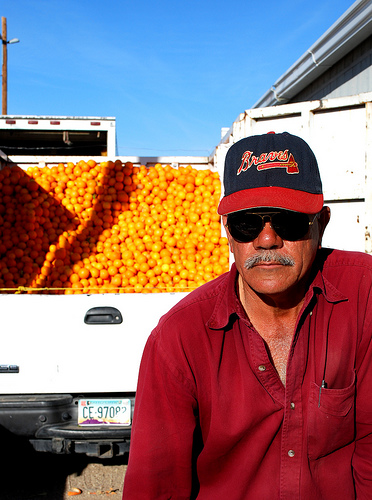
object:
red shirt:
[119, 247, 371, 499]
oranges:
[167, 234, 178, 249]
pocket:
[303, 368, 355, 463]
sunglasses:
[222, 210, 313, 245]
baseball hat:
[216, 129, 324, 218]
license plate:
[76, 395, 131, 423]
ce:
[82, 403, 96, 418]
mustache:
[242, 251, 294, 270]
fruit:
[150, 244, 161, 255]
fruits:
[112, 256, 123, 271]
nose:
[252, 222, 283, 254]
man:
[118, 131, 371, 499]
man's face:
[225, 211, 317, 296]